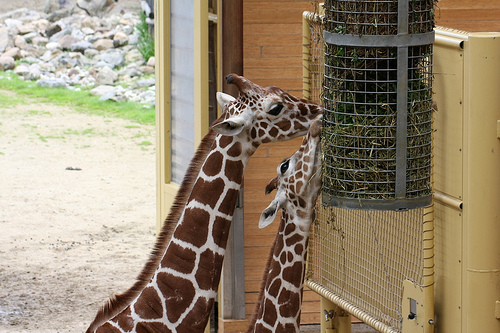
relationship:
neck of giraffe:
[264, 212, 305, 323] [99, 80, 321, 329]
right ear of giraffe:
[260, 177, 277, 194] [99, 80, 321, 329]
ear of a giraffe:
[256, 194, 286, 229] [99, 80, 321, 329]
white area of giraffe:
[236, 131, 251, 159] [99, 80, 321, 329]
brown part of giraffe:
[202, 151, 223, 175] [99, 80, 321, 329]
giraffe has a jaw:
[99, 80, 321, 329] [311, 124, 323, 195]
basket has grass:
[319, 0, 435, 210] [325, 3, 431, 196]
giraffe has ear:
[99, 80, 321, 329] [256, 194, 286, 229]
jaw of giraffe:
[311, 124, 323, 195] [99, 80, 321, 329]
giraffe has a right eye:
[99, 80, 321, 329] [265, 104, 284, 117]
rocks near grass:
[1, 0, 156, 106] [4, 69, 160, 128]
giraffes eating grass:
[84, 73, 331, 331] [325, 3, 431, 196]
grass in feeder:
[325, 3, 431, 196] [321, 0, 432, 210]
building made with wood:
[147, 2, 497, 333] [244, 3, 499, 326]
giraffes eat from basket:
[84, 73, 331, 331] [321, 0, 432, 210]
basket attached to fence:
[321, 0, 432, 210] [305, 6, 432, 331]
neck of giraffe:
[264, 212, 305, 323] [248, 109, 330, 333]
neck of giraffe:
[168, 142, 247, 299] [99, 80, 321, 329]